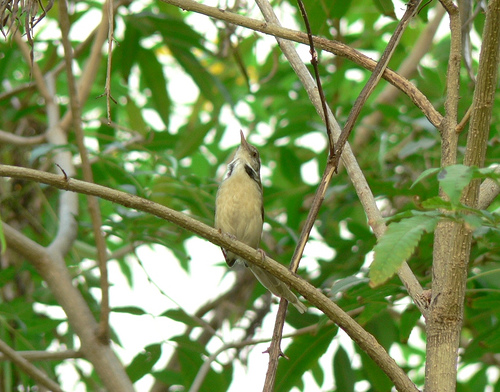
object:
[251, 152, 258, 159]
eye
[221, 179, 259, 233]
feathers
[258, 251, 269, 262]
foot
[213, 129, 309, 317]
bird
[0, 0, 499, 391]
tree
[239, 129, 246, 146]
beak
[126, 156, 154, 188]
leaves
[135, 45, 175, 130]
leaf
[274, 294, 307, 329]
leaves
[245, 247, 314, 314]
tail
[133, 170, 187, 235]
leaves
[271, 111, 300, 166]
leaf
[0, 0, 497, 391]
sky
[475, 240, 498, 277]
leaves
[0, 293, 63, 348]
leaves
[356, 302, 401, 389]
leaf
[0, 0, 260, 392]
branch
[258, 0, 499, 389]
branch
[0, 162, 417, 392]
limb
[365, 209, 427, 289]
leaf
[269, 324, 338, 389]
leaf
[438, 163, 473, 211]
leaf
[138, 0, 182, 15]
leaf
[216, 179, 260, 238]
chest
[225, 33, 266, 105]
leaf